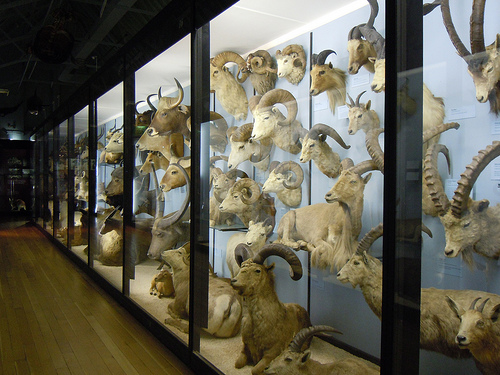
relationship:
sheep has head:
[259, 155, 307, 215] [255, 160, 302, 204]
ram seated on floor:
[220, 240, 316, 371] [28, 193, 379, 373]